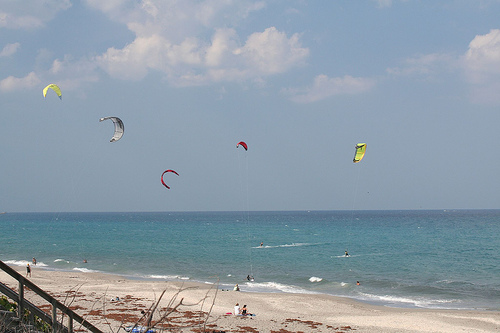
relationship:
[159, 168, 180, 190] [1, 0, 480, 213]
c-kite in sky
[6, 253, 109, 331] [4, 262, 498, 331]
railing leading to beach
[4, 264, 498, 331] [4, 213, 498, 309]
sand along an ocean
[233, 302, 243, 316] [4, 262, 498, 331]
person sitting on a beach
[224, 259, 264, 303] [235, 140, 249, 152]
person with c-kite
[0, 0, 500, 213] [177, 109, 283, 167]
sky with kites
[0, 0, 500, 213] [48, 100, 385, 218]
sky with kites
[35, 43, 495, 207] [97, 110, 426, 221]
sky with kites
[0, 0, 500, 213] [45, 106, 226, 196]
sky with kites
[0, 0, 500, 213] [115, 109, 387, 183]
sky with kites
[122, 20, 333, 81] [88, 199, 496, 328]
clouds above water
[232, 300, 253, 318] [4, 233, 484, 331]
people on beach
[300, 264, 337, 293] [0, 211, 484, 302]
wave in water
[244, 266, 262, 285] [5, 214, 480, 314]
person on water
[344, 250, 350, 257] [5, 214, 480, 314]
person on water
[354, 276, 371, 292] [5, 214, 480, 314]
person on water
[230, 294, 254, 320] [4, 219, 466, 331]
couple on beach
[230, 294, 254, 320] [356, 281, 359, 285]
couple watch person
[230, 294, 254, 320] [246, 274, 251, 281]
couple watch person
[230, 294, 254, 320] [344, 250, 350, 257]
couple watch person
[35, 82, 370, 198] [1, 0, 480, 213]
c-kites in sky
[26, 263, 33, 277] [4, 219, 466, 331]
person in beach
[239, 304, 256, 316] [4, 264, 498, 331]
people sitting on sand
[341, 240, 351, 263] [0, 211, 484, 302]
person in water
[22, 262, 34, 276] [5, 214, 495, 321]
person walking in beach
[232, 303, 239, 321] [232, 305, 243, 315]
person wearing top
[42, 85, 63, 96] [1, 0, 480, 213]
c-kite in sky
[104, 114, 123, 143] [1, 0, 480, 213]
c-kite in sky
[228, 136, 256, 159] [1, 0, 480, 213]
c-kite in sky